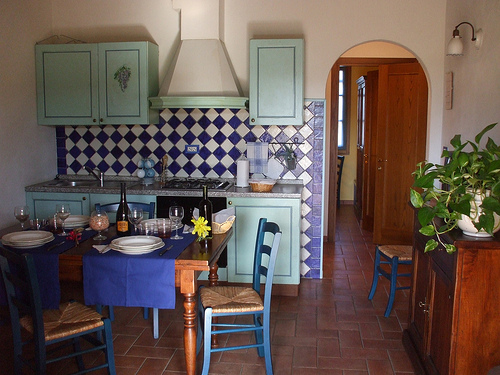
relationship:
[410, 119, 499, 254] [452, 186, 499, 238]
plant in pot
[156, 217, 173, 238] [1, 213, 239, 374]
glass on table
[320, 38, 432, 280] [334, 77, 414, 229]
arched walkway in room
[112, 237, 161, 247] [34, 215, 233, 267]
plate on table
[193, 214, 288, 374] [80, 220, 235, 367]
chair at table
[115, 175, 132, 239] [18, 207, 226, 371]
stemmed glass at table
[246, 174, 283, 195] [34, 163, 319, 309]
basket at counter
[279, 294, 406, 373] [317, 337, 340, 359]
floor has tile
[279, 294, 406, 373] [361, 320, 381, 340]
floor has tile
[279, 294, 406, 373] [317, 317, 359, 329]
floor has tile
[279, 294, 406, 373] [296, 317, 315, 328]
floor has tile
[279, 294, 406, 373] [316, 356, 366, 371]
floor has tile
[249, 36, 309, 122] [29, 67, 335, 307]
cabinet on wall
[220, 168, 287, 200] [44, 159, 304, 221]
basket on counter